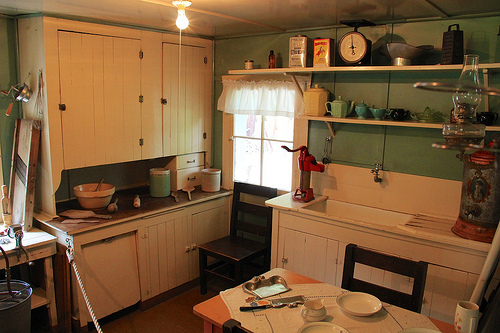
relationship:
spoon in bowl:
[88, 180, 105, 196] [47, 160, 151, 217]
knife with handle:
[236, 302, 276, 312] [238, 302, 268, 311]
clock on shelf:
[338, 30, 371, 62] [227, 62, 497, 76]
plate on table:
[335, 290, 382, 316] [193, 267, 458, 332]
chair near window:
[187, 179, 279, 303] [222, 85, 297, 194]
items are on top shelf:
[285, 33, 392, 72] [222, 63, 418, 73]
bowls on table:
[287, 278, 393, 330] [193, 267, 458, 332]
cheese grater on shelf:
[440, 21, 465, 63] [226, 62, 498, 74]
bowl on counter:
[73, 171, 100, 207] [45, 179, 234, 236]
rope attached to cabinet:
[58, 241, 113, 331] [66, 228, 142, 329]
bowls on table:
[287, 278, 393, 330] [195, 265, 471, 329]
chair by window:
[187, 179, 279, 303] [203, 75, 308, 220]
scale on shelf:
[334, 16, 374, 64] [228, 58, 498, 109]